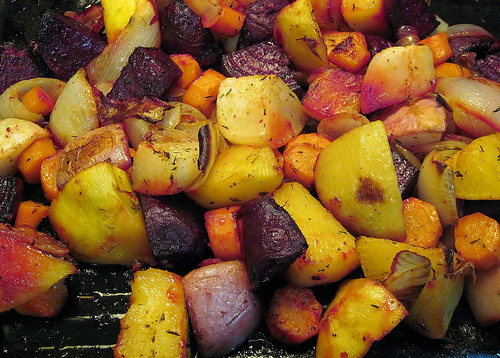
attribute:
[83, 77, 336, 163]
potatoes — multi-colored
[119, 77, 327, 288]
vegetables — multi-colored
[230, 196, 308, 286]
potato — purple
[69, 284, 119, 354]
grill — grates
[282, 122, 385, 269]
potatoes — yellow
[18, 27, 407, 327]
fruit — roasted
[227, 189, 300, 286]
fruit — purple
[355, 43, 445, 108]
fruit — yellow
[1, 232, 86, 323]
fruit — yellow, pink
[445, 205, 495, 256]
fruit — round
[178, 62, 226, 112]
fruit — orange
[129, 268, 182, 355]
food — yellow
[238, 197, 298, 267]
food — purple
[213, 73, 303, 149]
food — white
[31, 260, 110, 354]
grill — black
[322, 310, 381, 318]
food — orange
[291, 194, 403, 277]
food — orange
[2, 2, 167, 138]
onions — lightly grilled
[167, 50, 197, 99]
carrot — grilled, orange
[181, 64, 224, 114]
carrot — grilled, orange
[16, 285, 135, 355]
rods — metal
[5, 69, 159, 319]
vegetables — mixed, grilled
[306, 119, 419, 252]
lemon — grilled, yellow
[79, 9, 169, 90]
onion — white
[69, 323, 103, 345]
surface — black 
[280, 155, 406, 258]
potato — wedge 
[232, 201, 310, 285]
food — purple wedge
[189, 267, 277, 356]
onion — largest pink piece , bottom piece 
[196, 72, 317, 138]
potato — Middle , light yellow big chunk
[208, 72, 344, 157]
food —  largest chunk of yellow 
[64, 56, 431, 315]
food —  Burnt piece , top  , yellow wedge 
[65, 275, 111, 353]
pan — frying